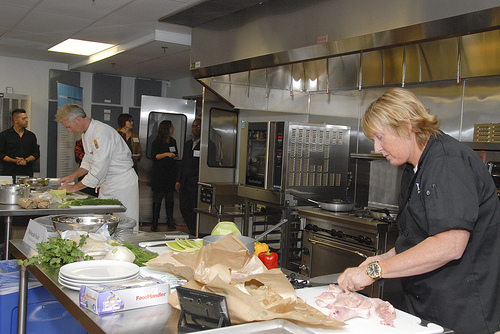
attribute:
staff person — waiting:
[177, 116, 202, 236]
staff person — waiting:
[148, 117, 181, 233]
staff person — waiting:
[109, 110, 142, 161]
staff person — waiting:
[0, 105, 41, 180]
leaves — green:
[30, 230, 79, 277]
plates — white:
[52, 252, 135, 293]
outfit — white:
[70, 115, 137, 216]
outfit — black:
[388, 132, 498, 319]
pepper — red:
[259, 248, 280, 278]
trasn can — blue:
[4, 255, 76, 331]